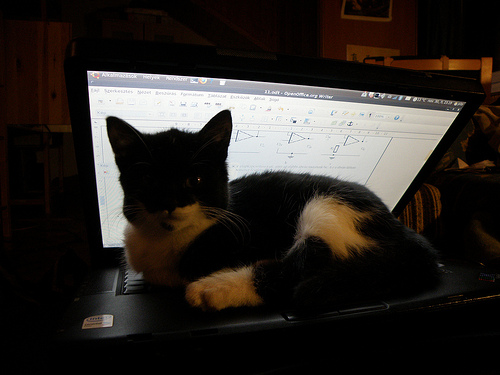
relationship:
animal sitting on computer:
[104, 108, 444, 312] [54, 37, 500, 343]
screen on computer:
[86, 71, 466, 248] [54, 37, 500, 343]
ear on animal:
[107, 111, 157, 181] [104, 108, 444, 312]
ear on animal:
[83, 102, 240, 158] [104, 108, 444, 312]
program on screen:
[95, 110, 404, 247] [86, 71, 466, 248]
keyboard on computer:
[120, 253, 181, 294] [53, 42, 498, 347]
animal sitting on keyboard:
[104, 108, 444, 312] [120, 253, 181, 294]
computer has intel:
[54, 37, 500, 343] [38, 76, 490, 336]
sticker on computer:
[81, 305, 118, 330] [54, 37, 500, 343]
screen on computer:
[86, 76, 466, 201] [54, 37, 500, 343]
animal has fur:
[104, 108, 456, 290] [107, 110, 437, 303]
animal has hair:
[104, 108, 444, 312] [241, 180, 443, 292]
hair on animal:
[157, 134, 203, 162] [104, 108, 444, 312]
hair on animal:
[209, 168, 426, 299] [104, 108, 444, 312]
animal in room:
[104, 108, 444, 312] [6, 8, 484, 346]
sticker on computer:
[82, 314, 114, 330] [54, 37, 500, 343]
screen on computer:
[86, 71, 466, 248] [53, 42, 498, 347]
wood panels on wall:
[0, 2, 70, 132] [1, 5, 499, 136]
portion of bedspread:
[413, 194, 484, 219] [406, 195, 441, 227]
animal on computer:
[104, 108, 444, 312] [54, 37, 500, 343]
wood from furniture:
[367, 53, 484, 73] [375, 55, 495, 85]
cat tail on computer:
[291, 217, 440, 313] [54, 37, 500, 343]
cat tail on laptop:
[291, 217, 440, 313] [49, 44, 484, 324]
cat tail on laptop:
[287, 208, 441, 304] [49, 44, 484, 324]